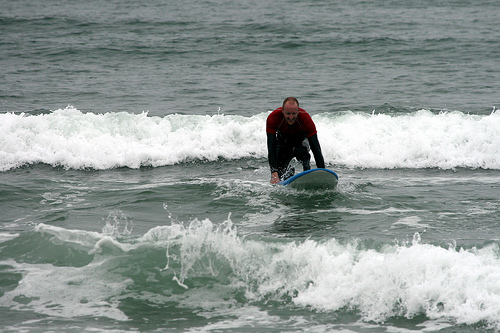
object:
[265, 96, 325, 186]
man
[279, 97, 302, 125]
head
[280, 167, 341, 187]
surfboard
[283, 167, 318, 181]
stripe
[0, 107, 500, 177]
wave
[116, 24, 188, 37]
ripple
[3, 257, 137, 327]
foam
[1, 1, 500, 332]
water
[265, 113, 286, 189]
right arm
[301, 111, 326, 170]
left arm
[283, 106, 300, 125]
face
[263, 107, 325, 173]
wetsuit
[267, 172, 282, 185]
hand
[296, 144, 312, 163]
knee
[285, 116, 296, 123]
mouth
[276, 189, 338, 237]
shadow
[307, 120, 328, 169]
sleeve